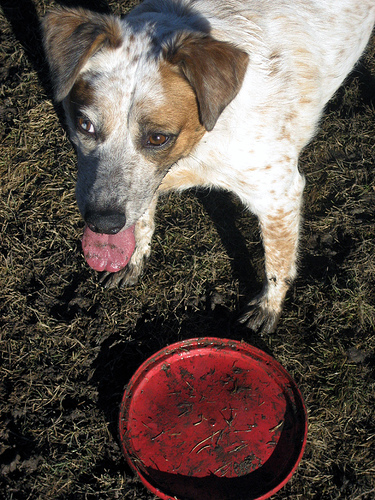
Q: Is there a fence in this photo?
A: No, there are no fences.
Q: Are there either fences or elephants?
A: No, there are no fences or elephants.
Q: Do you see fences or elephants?
A: No, there are no fences or elephants.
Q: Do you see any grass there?
A: Yes, there is grass.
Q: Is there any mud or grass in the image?
A: Yes, there is grass.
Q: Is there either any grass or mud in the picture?
A: Yes, there is grass.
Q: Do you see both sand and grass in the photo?
A: No, there is grass but no sand.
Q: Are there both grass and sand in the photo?
A: No, there is grass but no sand.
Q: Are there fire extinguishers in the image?
A: No, there are no fire extinguishers.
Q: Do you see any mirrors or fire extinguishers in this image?
A: No, there are no fire extinguishers or mirrors.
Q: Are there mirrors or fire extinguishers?
A: No, there are no fire extinguishers or mirrors.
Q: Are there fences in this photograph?
A: No, there are no fences.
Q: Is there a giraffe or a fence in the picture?
A: No, there are no fences or giraffes.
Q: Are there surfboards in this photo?
A: No, there are no surfboards.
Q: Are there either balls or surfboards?
A: No, there are no surfboards or balls.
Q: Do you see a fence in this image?
A: No, there are no fences.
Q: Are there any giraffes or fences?
A: No, there are no fences or giraffes.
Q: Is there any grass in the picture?
A: Yes, there is grass.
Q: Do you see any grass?
A: Yes, there is grass.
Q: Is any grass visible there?
A: Yes, there is grass.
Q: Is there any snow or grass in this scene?
A: Yes, there is grass.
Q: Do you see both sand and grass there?
A: No, there is grass but no sand.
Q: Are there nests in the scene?
A: No, there are no nests.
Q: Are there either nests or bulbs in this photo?
A: No, there are no nests or bulbs.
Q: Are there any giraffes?
A: No, there are no giraffes.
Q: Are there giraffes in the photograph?
A: No, there are no giraffes.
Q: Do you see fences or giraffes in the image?
A: No, there are no giraffes or fences.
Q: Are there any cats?
A: No, there are no cats.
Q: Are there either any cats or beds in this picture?
A: No, there are no cats or beds.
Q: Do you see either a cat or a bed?
A: No, there are no cats or beds.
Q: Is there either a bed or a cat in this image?
A: No, there are no cats or beds.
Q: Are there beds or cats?
A: No, there are no cats or beds.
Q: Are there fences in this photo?
A: No, there are no fences.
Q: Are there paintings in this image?
A: No, there are no paintings.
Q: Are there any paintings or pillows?
A: No, there are no paintings or pillows.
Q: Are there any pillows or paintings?
A: No, there are no paintings or pillows.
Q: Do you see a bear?
A: No, there are no bears.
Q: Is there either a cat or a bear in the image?
A: No, there are no bears or cats.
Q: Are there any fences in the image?
A: No, there are no fences.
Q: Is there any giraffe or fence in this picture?
A: No, there are no fences or giraffes.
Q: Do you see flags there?
A: No, there are no flags.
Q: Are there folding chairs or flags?
A: No, there are no flags or folding chairs.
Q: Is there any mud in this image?
A: Yes, there is mud.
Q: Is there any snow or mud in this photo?
A: Yes, there is mud.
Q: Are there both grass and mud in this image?
A: Yes, there are both mud and grass.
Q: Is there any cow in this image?
A: No, there are no cows.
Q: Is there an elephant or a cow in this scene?
A: No, there are no cows or elephants.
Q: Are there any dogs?
A: Yes, there is a dog.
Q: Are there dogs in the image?
A: Yes, there is a dog.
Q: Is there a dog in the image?
A: Yes, there is a dog.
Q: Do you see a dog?
A: Yes, there is a dog.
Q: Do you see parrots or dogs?
A: Yes, there is a dog.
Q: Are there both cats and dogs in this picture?
A: No, there is a dog but no cats.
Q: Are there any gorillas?
A: No, there are no gorillas.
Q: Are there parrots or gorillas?
A: No, there are no gorillas or parrots.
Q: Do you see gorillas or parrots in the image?
A: No, there are no gorillas or parrots.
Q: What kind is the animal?
A: The animal is a dog.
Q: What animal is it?
A: The animal is a dog.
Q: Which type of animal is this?
A: This is a dog.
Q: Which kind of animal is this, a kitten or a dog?
A: This is a dog.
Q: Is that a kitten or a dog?
A: That is a dog.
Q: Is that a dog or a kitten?
A: That is a dog.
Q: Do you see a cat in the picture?
A: No, there are no cats.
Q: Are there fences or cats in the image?
A: No, there are no cats or fences.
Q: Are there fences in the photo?
A: No, there are no fences.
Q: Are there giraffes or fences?
A: No, there are no fences or giraffes.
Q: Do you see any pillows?
A: No, there are no pillows.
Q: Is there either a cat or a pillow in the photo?
A: No, there are no pillows or cats.